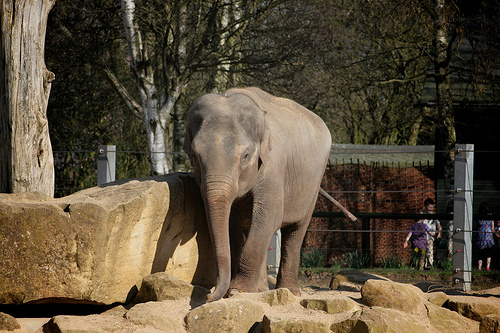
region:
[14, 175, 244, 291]
The big rock to the left of the elephant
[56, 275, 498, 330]
The elephant is walking on rocks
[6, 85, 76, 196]
The tree trunk behind the big rock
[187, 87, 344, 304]
The elephant is a young baby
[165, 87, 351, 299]
The elephant is gray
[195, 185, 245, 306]
The trunk of the elephant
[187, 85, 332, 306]
A gray elephant on a rock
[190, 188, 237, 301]
A trunk on an elephant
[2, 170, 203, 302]
A large rock beside an elephant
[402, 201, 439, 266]
Children playing near an elephant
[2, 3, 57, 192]
A tall tree trunk near an elephant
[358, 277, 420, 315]
A rock near an elephant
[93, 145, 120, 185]
Gray post near a large rock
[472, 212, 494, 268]
A little girl outside a fence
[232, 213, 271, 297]
Front leg on an elephant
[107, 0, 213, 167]
A white birch tree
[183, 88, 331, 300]
an african elephant walking forward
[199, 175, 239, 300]
the trunk of an elephant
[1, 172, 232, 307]
a rock wall in an enclosure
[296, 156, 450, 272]
black metal spikes in a fence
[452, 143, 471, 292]
a wood and metal post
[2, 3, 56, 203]
an old cracked tree trunk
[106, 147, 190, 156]
a gray metal wire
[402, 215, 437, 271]
a child wearing a purple shirt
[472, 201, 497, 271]
a girl in a dress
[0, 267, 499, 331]
rocks along the ground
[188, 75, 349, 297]
An elephant standing on rocks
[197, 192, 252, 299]
An elephant trunk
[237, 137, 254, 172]
Eye of an elephant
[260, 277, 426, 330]
Rock boulders in the photo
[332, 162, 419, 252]
A fence in the background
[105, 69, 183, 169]
A tree trunk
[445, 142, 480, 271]
A metal pole on the fence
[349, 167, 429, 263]
Wire mesh on the fence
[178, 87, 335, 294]
a gray elephant on rocks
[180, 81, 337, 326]
an elephant standing on boulders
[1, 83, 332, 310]
a large rock by an elephant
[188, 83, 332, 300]
a gray and tan colored elephant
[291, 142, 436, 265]
a red brick building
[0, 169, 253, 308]
a large rock wall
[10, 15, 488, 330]
a scene during the day time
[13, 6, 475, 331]
a scene outside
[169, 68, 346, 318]
a elephant standing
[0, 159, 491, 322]
gray stones here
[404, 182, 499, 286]
people in the background